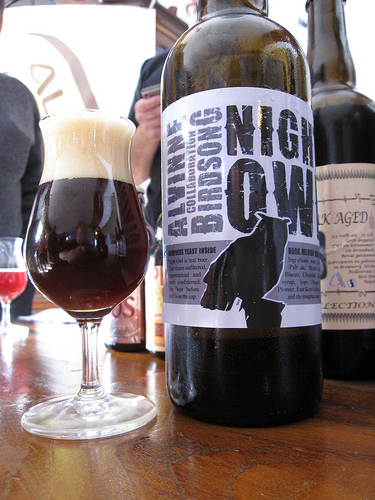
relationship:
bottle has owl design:
[156, 2, 322, 430] [199, 211, 298, 337]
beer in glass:
[31, 175, 148, 314] [16, 105, 171, 443]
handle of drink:
[68, 320, 109, 394] [7, 103, 165, 453]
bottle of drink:
[160, 0, 322, 430] [21, 107, 159, 442]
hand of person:
[135, 91, 162, 140] [128, 2, 239, 253]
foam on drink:
[34, 107, 150, 195] [19, 102, 157, 481]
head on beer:
[53, 115, 119, 187] [19, 118, 149, 311]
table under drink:
[0, 321, 372, 498] [21, 107, 159, 442]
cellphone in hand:
[112, 41, 203, 162] [127, 92, 180, 145]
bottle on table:
[156, 2, 322, 430] [0, 321, 372, 498]